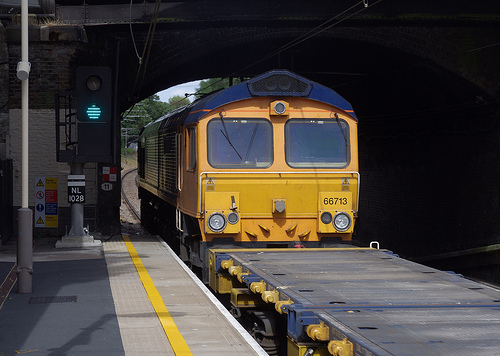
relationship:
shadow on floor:
[0, 247, 189, 356] [0, 233, 269, 355]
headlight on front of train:
[208, 212, 224, 234] [134, 59, 374, 256]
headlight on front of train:
[333, 208, 353, 232] [134, 59, 374, 256]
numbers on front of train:
[319, 192, 350, 207] [134, 59, 374, 256]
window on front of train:
[280, 116, 353, 173] [134, 59, 374, 256]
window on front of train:
[206, 117, 276, 170] [134, 59, 374, 256]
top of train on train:
[141, 67, 357, 128] [134, 59, 374, 256]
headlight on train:
[208, 212, 224, 234] [134, 59, 374, 256]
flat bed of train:
[191, 235, 499, 354] [134, 59, 374, 256]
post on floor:
[10, 0, 40, 299] [0, 233, 269, 355]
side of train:
[132, 102, 203, 209] [134, 59, 374, 256]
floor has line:
[0, 233, 269, 355] [119, 228, 194, 354]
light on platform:
[83, 102, 106, 121] [0, 0, 270, 355]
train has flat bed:
[134, 59, 374, 256] [191, 235, 499, 354]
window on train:
[280, 116, 353, 173] [134, 59, 374, 256]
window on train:
[206, 117, 276, 170] [134, 59, 374, 256]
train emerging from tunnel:
[134, 59, 374, 256] [63, 5, 500, 252]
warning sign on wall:
[32, 175, 62, 229] [0, 27, 126, 236]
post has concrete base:
[10, 0, 40, 299] [16, 205, 37, 298]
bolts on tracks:
[216, 255, 352, 356] [191, 235, 499, 354]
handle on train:
[191, 164, 367, 215] [134, 59, 374, 256]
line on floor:
[119, 228, 194, 354] [0, 233, 269, 355]